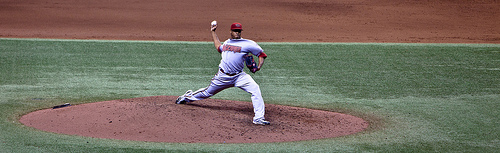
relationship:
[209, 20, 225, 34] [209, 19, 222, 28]
hand holding ball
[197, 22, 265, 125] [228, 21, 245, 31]
man wearing cap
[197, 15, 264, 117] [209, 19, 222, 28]
man holding ball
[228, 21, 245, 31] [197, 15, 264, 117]
cap on man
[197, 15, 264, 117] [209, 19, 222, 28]
man about to throw ball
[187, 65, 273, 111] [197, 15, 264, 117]
legs of man